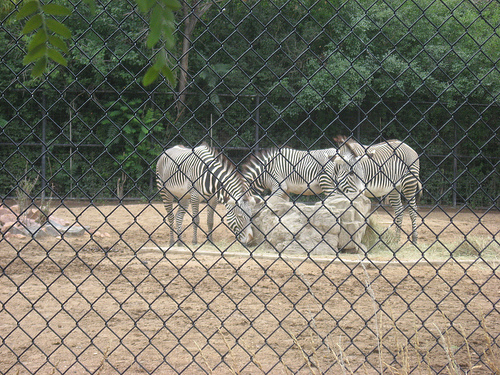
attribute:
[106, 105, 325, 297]
zebra — looking for food 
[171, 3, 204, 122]
branch — tall, brown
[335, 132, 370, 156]
mane — black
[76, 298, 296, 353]
dirt — brown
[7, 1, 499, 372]
fence — wire mesh, grey, chain link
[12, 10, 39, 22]
leaf — green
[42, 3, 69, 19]
leaf — green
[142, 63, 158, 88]
leaf — green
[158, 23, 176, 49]
leaf — green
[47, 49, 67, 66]
leaf — green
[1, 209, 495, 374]
ground — bare, brown, dirt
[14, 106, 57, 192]
pole — black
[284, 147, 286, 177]
stripe — Black, white 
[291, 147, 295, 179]
stripe — Black, white 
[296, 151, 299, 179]
stripe — Black, white 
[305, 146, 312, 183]
stripe — Black, white 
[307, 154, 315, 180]
stripe — Black, white 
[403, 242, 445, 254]
grass — dry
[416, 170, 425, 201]
tail — white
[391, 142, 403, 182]
stripes — black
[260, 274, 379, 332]
grass — brown, dry